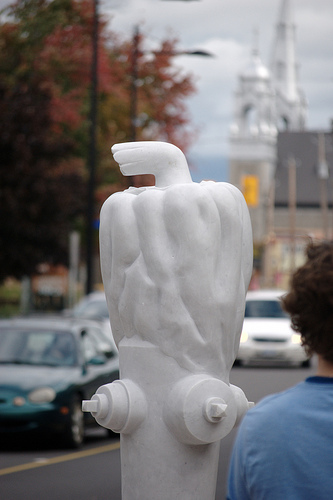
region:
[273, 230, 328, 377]
The head of a person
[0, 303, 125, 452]
A dark green car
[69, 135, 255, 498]
A large white post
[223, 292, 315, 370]
A white car with its lights on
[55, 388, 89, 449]
A tire of a car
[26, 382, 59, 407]
The headlight of a car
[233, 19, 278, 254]
A tall white tower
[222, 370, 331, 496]
A sky blue shirt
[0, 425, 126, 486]
A yellow line on the road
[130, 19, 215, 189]
A large black lamp post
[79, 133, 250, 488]
the hydrant is white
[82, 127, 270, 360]
The hydrant has a large top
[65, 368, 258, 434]
The hydrant has 3 entries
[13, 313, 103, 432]
the car is blue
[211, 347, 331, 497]
His shirt is blue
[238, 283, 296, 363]
The car is white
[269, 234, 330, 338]
his hair is brown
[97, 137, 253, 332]
the hydrant is decorated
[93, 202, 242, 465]
the hydrant is smooth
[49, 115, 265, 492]
white statue in the middle of the street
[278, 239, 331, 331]
person with brown hair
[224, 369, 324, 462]
person wearing a blue shirt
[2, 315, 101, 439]
green car driving down the street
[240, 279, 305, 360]
white car on the street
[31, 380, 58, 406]
head lights on a car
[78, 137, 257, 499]
the modern art statue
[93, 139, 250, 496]
the modern art sculpture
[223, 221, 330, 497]
person wearing t shirt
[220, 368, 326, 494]
the t shirt is blue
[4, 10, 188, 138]
the tree with brown leaves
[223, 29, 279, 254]
the tower in the background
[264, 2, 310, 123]
steeple behind the tower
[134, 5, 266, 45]
clouds in the sky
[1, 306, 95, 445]
the car in the street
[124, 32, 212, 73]
street light above the street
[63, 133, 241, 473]
a large white statue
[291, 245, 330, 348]
the brown hair of a person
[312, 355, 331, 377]
the neck of a person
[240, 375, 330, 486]
the blue shirt of a person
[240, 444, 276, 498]
the wrinkles on a persons shirt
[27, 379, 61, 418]
the headlights on a car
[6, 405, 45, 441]
the front bumper of a car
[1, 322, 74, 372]
the windshield of a car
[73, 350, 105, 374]
a cars side view mirror